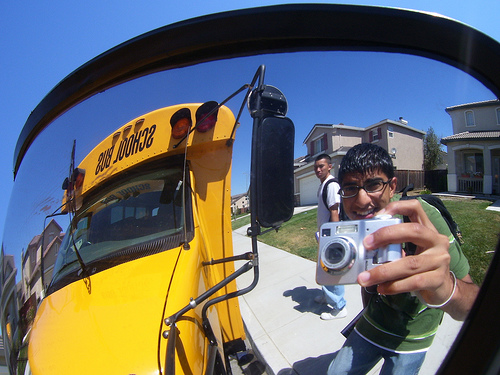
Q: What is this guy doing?
A: Taking a pic.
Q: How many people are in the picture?
A: 2.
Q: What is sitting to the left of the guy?
A: School bus.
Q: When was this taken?
A: During the day.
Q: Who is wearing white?
A: Guy behind the photographer.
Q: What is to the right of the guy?
A: Homes.